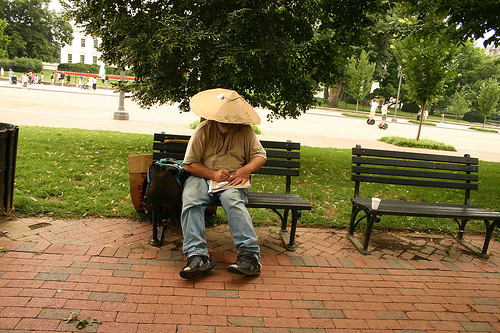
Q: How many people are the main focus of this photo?
A: One.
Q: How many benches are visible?
A: Two.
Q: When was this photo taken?
A: Outside, during the daytime.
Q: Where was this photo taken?
A: At a park.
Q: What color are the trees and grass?
A: Green.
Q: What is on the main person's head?
A: A hat.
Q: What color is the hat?
A: Tan.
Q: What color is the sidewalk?
A: Red.